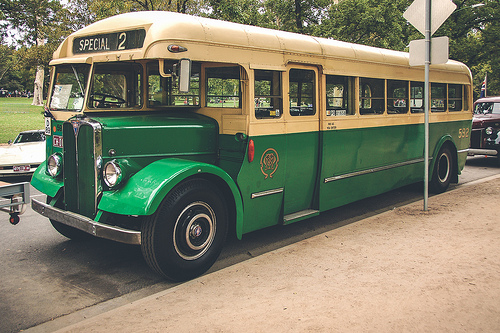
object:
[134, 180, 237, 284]
blackwheels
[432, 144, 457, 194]
blackwheels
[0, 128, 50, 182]
sports car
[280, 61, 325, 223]
door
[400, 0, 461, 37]
sign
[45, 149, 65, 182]
headlights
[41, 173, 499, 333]
bus stop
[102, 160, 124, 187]
headlight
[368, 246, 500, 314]
sand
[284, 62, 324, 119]
window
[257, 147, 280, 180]
logo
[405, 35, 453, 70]
sign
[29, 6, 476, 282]
bus